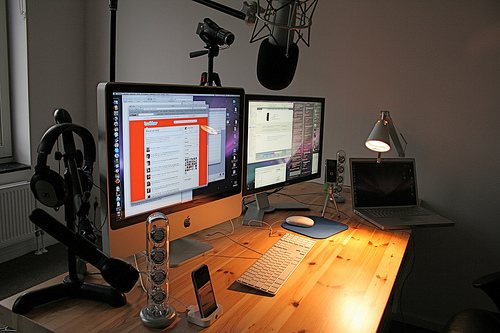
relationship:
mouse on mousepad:
[285, 215, 315, 227] [284, 216, 347, 239]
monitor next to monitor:
[245, 88, 330, 212] [93, 74, 253, 264]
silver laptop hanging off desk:
[348, 156, 458, 232] [0, 180, 420, 329]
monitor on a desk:
[245, 90, 328, 200] [29, 205, 416, 331]